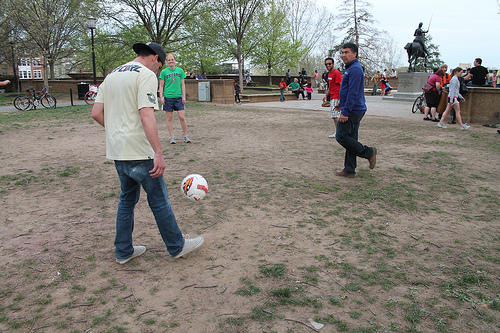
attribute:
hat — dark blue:
[131, 37, 170, 66]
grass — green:
[235, 157, 399, 248]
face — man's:
[322, 58, 336, 71]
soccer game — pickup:
[169, 158, 237, 213]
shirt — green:
[157, 67, 186, 99]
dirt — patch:
[1, 98, 498, 329]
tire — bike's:
[411, 94, 424, 111]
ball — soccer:
[179, 172, 209, 202]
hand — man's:
[148, 152, 165, 177]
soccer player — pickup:
[153, 48, 198, 147]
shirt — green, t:
[162, 66, 184, 99]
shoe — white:
[163, 223, 214, 258]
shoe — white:
[168, 235, 209, 256]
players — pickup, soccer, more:
[315, 42, 385, 187]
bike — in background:
[1, 84, 58, 114]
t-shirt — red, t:
[324, 68, 341, 98]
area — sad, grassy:
[30, 111, 426, 329]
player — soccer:
[313, 44, 347, 141]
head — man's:
[127, 29, 173, 88]